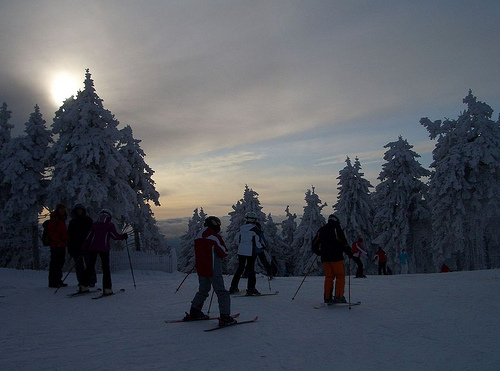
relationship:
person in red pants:
[313, 212, 363, 309] [323, 261, 347, 301]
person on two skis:
[313, 212, 363, 309] [316, 300, 364, 309]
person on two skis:
[183, 216, 238, 338] [165, 310, 258, 333]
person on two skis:
[76, 208, 129, 293] [67, 285, 126, 302]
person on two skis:
[227, 211, 266, 293] [227, 286, 280, 298]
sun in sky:
[52, 70, 85, 105] [2, 1, 498, 220]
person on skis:
[313, 212, 363, 309] [318, 303, 365, 308]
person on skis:
[183, 216, 238, 338] [165, 310, 258, 333]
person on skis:
[76, 208, 129, 293] [67, 285, 126, 302]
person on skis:
[227, 211, 266, 293] [227, 286, 280, 298]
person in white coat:
[227, 211, 266, 293] [232, 222, 264, 257]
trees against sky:
[1, 69, 500, 274] [2, 1, 498, 220]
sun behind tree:
[52, 70, 85, 105] [48, 67, 143, 273]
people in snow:
[42, 201, 413, 333] [2, 264, 500, 370]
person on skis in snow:
[313, 212, 363, 309] [2, 264, 500, 370]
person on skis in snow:
[183, 216, 238, 338] [2, 264, 500, 370]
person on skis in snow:
[76, 208, 129, 293] [2, 264, 500, 370]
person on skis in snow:
[227, 211, 266, 293] [2, 264, 500, 370]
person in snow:
[183, 216, 238, 338] [2, 264, 500, 370]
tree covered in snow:
[48, 67, 143, 273] [1, 68, 170, 269]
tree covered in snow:
[414, 89, 499, 270] [420, 89, 500, 270]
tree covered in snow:
[370, 134, 431, 272] [371, 134, 430, 276]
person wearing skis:
[313, 212, 363, 309] [318, 303, 365, 308]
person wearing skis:
[183, 216, 238, 338] [165, 310, 258, 333]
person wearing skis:
[76, 208, 129, 293] [67, 285, 126, 302]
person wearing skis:
[227, 211, 266, 293] [227, 286, 280, 298]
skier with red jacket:
[193, 215, 231, 280] [195, 226, 229, 282]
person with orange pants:
[313, 212, 363, 309] [323, 261, 347, 301]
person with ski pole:
[313, 212, 363, 309] [346, 253, 354, 310]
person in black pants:
[227, 211, 266, 293] [231, 254, 256, 294]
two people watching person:
[43, 202, 93, 288] [76, 208, 129, 293]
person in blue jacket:
[396, 248, 411, 275] [400, 248, 411, 263]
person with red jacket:
[183, 216, 238, 338] [195, 226, 229, 282]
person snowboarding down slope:
[350, 237, 368, 279] [2, 264, 500, 370]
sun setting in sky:
[52, 70, 85, 105] [2, 1, 498, 220]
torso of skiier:
[440, 261, 451, 274] [440, 263, 450, 272]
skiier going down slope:
[440, 263, 450, 272] [2, 264, 500, 370]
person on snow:
[313, 212, 363, 309] [2, 264, 500, 370]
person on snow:
[183, 216, 238, 338] [2, 264, 500, 370]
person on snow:
[76, 208, 129, 293] [2, 264, 500, 370]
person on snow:
[227, 211, 266, 293] [2, 264, 500, 370]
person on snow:
[350, 237, 368, 279] [2, 264, 500, 370]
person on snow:
[396, 248, 411, 275] [2, 264, 500, 370]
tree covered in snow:
[293, 184, 330, 277] [292, 184, 330, 276]